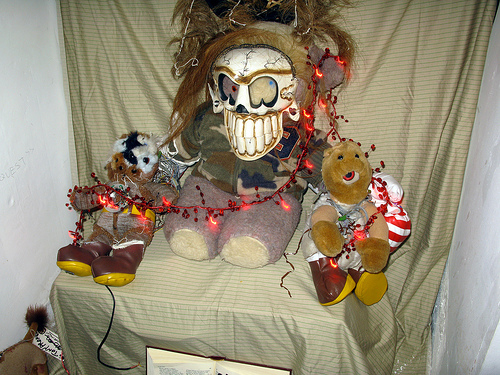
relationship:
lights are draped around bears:
[69, 43, 384, 268] [47, 15, 400, 307]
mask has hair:
[203, 43, 303, 160] [163, 3, 365, 80]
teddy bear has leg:
[156, 18, 338, 268] [227, 210, 289, 283]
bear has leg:
[168, 25, 329, 257] [222, 214, 296, 266]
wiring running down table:
[101, 288, 123, 351] [117, 242, 326, 371]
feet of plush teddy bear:
[160, 172, 302, 268] [156, 21, 345, 268]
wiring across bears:
[138, 74, 373, 225] [44, 7, 422, 294]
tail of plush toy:
[22, 307, 47, 340] [0, 303, 51, 373]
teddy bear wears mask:
[156, 18, 338, 268] [201, 40, 299, 166]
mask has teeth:
[156, 0, 357, 162] [215, 87, 280, 171]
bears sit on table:
[50, 12, 439, 315] [52, 228, 406, 364]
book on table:
[142, 344, 290, 373] [52, 225, 350, 373]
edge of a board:
[280, 303, 308, 335] [65, 211, 349, 368]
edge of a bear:
[336, 246, 353, 260] [300, 142, 391, 308]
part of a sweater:
[346, 256, 356, 265] [304, 197, 370, 264]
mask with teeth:
[156, 0, 357, 162] [219, 111, 279, 151]